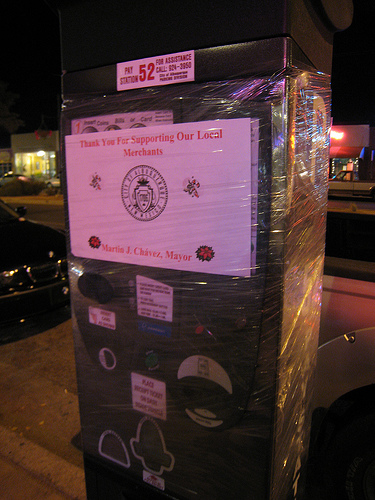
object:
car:
[0, 182, 68, 338]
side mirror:
[14, 206, 28, 218]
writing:
[79, 128, 222, 157]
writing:
[115, 50, 194, 92]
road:
[0, 180, 371, 285]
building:
[0, 122, 370, 196]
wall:
[62, 125, 278, 189]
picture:
[121, 164, 168, 223]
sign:
[65, 110, 255, 280]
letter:
[116, 49, 195, 91]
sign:
[115, 50, 194, 92]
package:
[56, 0, 336, 492]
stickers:
[84, 262, 233, 492]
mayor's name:
[101, 242, 192, 267]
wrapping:
[57, 35, 331, 497]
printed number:
[138, 62, 155, 82]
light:
[328, 129, 343, 140]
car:
[0, 170, 41, 196]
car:
[324, 165, 372, 200]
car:
[44, 172, 66, 189]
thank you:
[79, 138, 114, 148]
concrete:
[0, 318, 79, 496]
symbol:
[120, 165, 167, 222]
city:
[134, 176, 153, 213]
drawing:
[194, 244, 215, 262]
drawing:
[87, 235, 101, 250]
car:
[300, 324, 375, 492]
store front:
[10, 130, 60, 183]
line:
[21, 215, 67, 237]